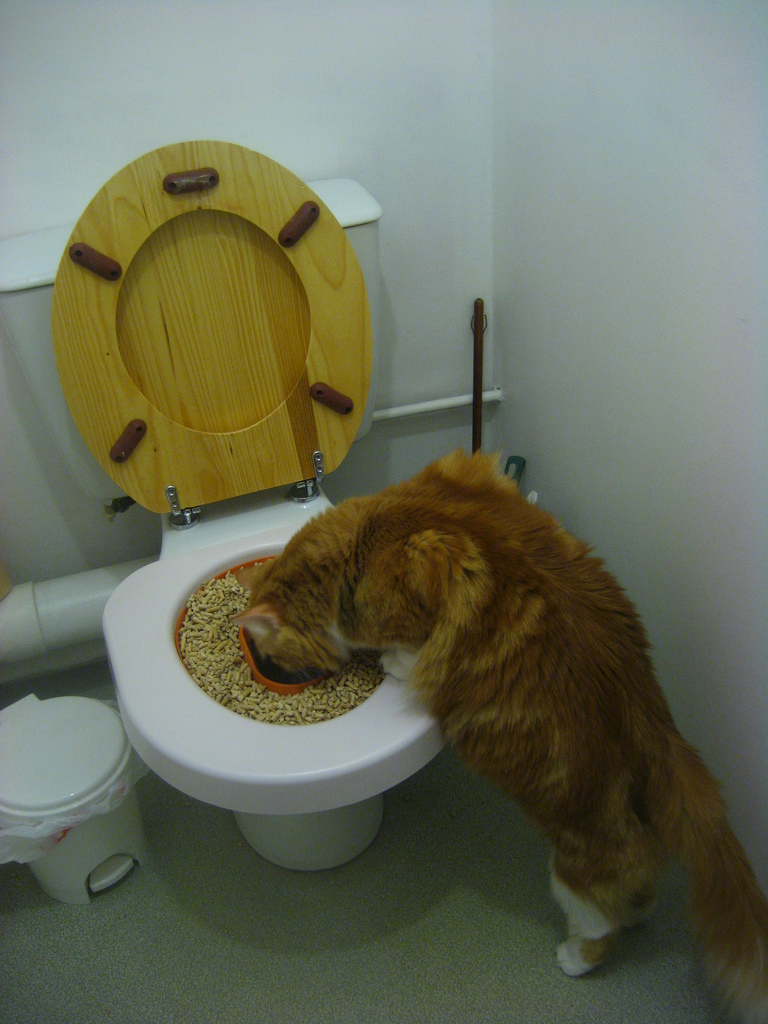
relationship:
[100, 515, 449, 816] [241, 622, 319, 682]
toilet bowl with cat food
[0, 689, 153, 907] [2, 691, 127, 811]
trash can with cover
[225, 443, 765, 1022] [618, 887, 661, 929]
cat standing on foot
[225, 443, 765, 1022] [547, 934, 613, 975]
cat standing on foot